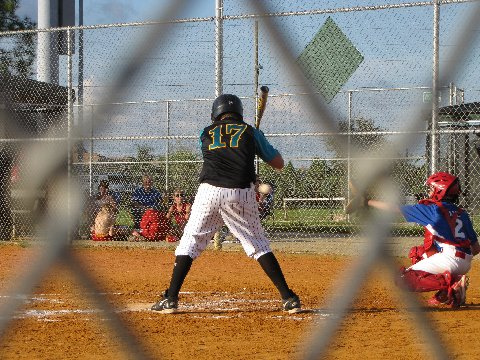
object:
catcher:
[344, 171, 480, 312]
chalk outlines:
[0, 288, 336, 325]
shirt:
[197, 116, 280, 190]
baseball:
[258, 183, 274, 195]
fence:
[1, 0, 480, 260]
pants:
[173, 182, 273, 262]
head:
[172, 187, 185, 202]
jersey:
[400, 202, 479, 255]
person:
[165, 191, 192, 240]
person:
[88, 202, 128, 240]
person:
[129, 207, 172, 242]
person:
[129, 172, 166, 229]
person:
[92, 182, 117, 208]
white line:
[0, 289, 333, 323]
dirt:
[0, 245, 480, 360]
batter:
[151, 92, 303, 316]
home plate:
[127, 301, 187, 315]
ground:
[0, 242, 480, 360]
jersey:
[198, 117, 280, 190]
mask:
[417, 179, 441, 206]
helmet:
[425, 171, 462, 201]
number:
[208, 123, 248, 150]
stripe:
[242, 204, 244, 217]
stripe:
[245, 191, 248, 202]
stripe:
[230, 189, 232, 196]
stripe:
[226, 191, 228, 197]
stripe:
[231, 203, 234, 210]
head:
[97, 179, 110, 196]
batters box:
[0, 287, 340, 325]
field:
[0, 240, 479, 360]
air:
[0, 0, 480, 171]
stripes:
[173, 220, 217, 260]